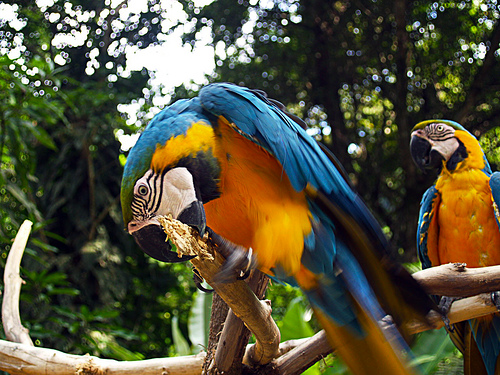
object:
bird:
[405, 118, 500, 375]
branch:
[395, 254, 495, 289]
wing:
[414, 187, 441, 269]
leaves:
[0, 0, 189, 359]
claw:
[190, 226, 258, 292]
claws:
[432, 294, 457, 316]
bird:
[117, 80, 451, 374]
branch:
[152, 215, 281, 374]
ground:
[388, 118, 441, 173]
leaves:
[281, 83, 315, 115]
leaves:
[180, 0, 261, 44]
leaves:
[438, 78, 463, 96]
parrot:
[400, 118, 499, 375]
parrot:
[115, 68, 410, 339]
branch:
[3, 220, 287, 368]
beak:
[129, 197, 209, 262]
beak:
[409, 136, 445, 174]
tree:
[0, 0, 500, 373]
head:
[409, 118, 486, 177]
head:
[118, 166, 210, 263]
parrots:
[117, 81, 438, 375]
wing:
[195, 78, 440, 312]